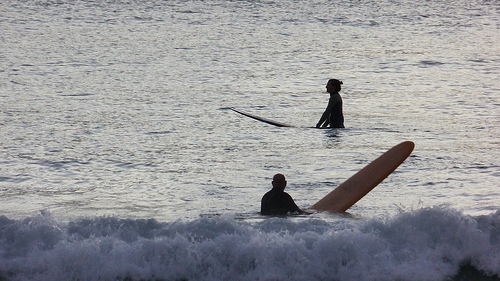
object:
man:
[258, 173, 307, 215]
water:
[0, 0, 500, 280]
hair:
[328, 78, 344, 92]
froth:
[0, 198, 500, 281]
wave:
[7, 151, 500, 281]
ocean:
[0, 0, 500, 281]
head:
[324, 78, 343, 93]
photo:
[0, 0, 500, 280]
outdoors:
[0, 1, 499, 279]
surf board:
[310, 140, 415, 211]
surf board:
[230, 108, 295, 128]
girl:
[315, 79, 345, 129]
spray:
[0, 202, 499, 281]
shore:
[0, 230, 500, 281]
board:
[227, 105, 294, 126]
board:
[309, 141, 415, 213]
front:
[229, 105, 297, 127]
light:
[343, 15, 497, 56]